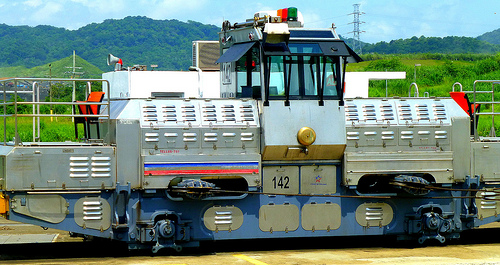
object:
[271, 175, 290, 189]
number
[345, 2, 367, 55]
radio tower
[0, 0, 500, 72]
background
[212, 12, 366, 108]
driver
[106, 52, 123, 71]
horn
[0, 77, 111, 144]
metal fence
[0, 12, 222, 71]
mountain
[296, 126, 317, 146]
bell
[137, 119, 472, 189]
side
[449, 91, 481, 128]
chair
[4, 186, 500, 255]
bottom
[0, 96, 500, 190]
silver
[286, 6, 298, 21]
green light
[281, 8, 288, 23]
red light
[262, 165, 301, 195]
vehicle window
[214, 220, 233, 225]
vents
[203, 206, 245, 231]
octagonal placement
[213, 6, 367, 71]
top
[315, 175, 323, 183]
star logo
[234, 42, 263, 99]
window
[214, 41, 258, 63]
blue teal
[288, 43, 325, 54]
windows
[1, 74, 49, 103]
parking lot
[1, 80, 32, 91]
few vehicles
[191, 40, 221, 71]
air conditioner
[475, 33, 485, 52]
trees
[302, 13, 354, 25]
electric wires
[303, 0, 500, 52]
air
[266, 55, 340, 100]
window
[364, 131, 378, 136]
vents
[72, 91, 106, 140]
chair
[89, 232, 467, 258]
train tracks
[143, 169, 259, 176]
stripe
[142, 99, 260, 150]
air vents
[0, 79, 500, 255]
structure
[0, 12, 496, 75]
wooded hills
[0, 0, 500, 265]
area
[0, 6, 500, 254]
vehicle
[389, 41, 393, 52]
trees